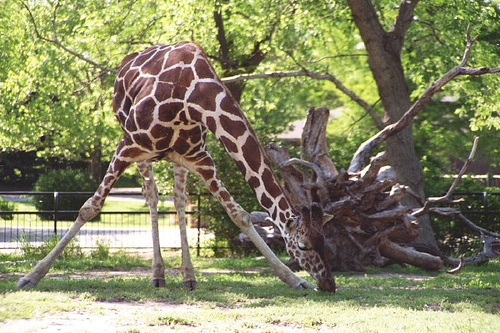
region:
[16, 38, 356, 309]
a tall giraffe bending down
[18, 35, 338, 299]
a tall giraffe eating grass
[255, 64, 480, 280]
a huge dead tree trunk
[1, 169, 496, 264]
a black fence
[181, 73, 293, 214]
a giraffe's long neck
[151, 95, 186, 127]
a brown and white spot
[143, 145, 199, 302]
a pair of back legs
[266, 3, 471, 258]
a medium sized tree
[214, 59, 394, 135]
a brown tree branch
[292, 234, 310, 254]
a giraffe's eye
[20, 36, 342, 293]
giraffe with spraddle legs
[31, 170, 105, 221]
dark green shrub in background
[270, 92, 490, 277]
twisted tree branches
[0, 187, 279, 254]
black fence behind giraffe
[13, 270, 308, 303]
hooves of giraffe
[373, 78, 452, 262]
tree trunk behind twisted branches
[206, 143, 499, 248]
shrubs along fence line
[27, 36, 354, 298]
giraffe grazing on grass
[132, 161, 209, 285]
back legs of giraffe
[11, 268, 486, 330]
grass giraffe is grazing from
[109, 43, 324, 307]
brown and tan spotted giraffe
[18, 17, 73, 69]
green leaves on brown branches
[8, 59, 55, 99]
green leaves on brown branches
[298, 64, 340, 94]
green leaves on brown branches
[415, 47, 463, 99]
green leaves on brown branches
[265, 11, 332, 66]
green leaves on brown branches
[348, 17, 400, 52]
green leaves on brown branches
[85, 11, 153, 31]
green leaves on brown branches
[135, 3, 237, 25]
green leaves on brown branches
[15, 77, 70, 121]
green leaves on brown branches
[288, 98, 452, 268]
weathered roots on a fallen tree trunk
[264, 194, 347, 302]
brown and white head of girraffe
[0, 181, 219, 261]
black metal fencing at side of road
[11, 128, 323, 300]
brown and white splayed legs of giraffe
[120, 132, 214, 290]
white and brown back legs of giraffe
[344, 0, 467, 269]
large trees with green background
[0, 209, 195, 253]
gray roadway behind metal fencing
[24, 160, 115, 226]
green round busy at the side of the road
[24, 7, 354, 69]
sunlight filtering through green leaves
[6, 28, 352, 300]
giraffe eats green grass near the sunlight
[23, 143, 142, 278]
front leg of giraffe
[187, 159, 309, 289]
front leg of giraffe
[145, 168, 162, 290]
back leg of giraffe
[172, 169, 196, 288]
back leg of giraffe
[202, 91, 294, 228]
neck of giraffe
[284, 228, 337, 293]
head of a giraffe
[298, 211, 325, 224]
horns on head of giraffe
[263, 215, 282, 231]
ear of a giraffe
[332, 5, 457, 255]
tree beside giraffe and fence